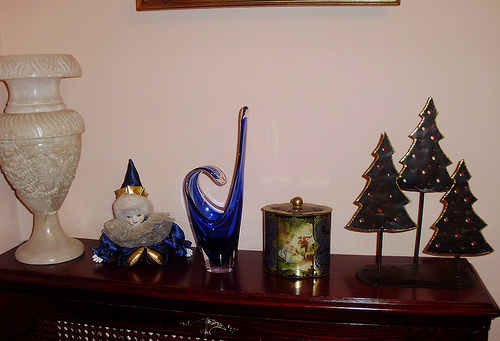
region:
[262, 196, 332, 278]
Blue and gold decorative container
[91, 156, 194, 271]
Antique porcelain clown doll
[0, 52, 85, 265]
Etched marble decorative vase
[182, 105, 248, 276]
Dark blue glass decorative sculpture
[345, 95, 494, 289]
Painted metal Christmas tree decoration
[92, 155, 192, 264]
Collectible harlequin doll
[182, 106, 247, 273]
Blown glass sculpture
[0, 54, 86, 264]
Beige Grecian marble urn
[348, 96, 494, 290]
Green pine trees with red ornaments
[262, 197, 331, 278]
Small jar with painted scene of a family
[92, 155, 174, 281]
Puppett with blue and gold hat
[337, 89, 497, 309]
Christmas tree decorations in shelf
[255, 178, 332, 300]
Small decoraticve tin on shelf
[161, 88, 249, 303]
Large glass ornament on shelf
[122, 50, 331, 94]
Basic white walls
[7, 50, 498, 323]
Decorations on a sofa table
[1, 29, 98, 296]
Large white decorative vase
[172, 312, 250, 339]
Lovely wooden handle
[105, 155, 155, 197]
Blue and gold hat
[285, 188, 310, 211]
small circle object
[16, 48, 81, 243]
White vase on shelf.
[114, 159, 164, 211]
Blue hat on doll on shelf.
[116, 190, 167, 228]
Doll has white hair.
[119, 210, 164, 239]
Doll has white face.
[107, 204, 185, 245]
Large sheer collar on doll.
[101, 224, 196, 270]
Doll is wearing blue outfit.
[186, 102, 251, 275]
Blue glass art on shelf.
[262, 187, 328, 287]
Multi colored container on shelf.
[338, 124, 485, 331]
Decorative trees on shelf.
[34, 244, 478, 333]
Wood shelf near wall.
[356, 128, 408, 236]
A green plastic tree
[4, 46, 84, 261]
A white ceramic vase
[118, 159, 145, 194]
A small blue and gold hat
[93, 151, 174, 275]
A doll in a blue and gold hat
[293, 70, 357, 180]
The wall behind the mantle is white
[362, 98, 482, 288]
Three plastic christmas trees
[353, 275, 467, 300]
The mantle is brown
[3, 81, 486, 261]
Assorted items on a mantle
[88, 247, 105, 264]
The right hand of the doll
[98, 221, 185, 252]
The doll is wearing a blue dress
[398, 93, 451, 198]
a metal christmas tree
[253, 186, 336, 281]
a trinket box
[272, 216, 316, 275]
two younge women sitting and a man standing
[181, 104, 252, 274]
a blue glass sculpture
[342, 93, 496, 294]
three metal christmas trees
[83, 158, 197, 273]
a porclen clown doll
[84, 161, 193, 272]
a porclen doll in a blue outfit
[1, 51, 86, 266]
a pretty white vase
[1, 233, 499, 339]
a dark brown table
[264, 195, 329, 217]
the top of a trinket box